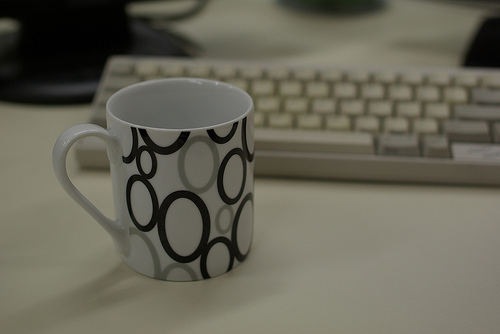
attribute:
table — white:
[0, 0, 496, 332]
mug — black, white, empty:
[50, 76, 255, 282]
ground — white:
[428, 111, 449, 128]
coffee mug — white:
[52, 72, 295, 297]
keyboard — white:
[99, 42, 499, 222]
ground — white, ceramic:
[392, 197, 419, 244]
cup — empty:
[99, 86, 259, 281]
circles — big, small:
[132, 139, 251, 265]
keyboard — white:
[95, 39, 498, 197]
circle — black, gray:
[178, 135, 218, 192]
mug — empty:
[47, 68, 264, 287]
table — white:
[342, 189, 486, 294]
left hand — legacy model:
[280, 60, 472, 175]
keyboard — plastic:
[228, 30, 498, 175]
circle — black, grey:
[156, 189, 209, 262]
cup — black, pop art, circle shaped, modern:
[44, 73, 259, 284]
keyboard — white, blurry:
[75, 55, 498, 189]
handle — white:
[53, 120, 116, 238]